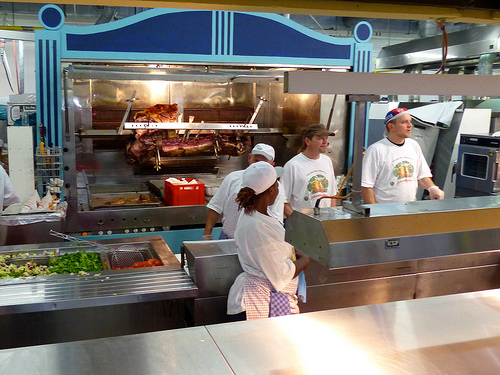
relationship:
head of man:
[391, 106, 415, 138] [353, 92, 451, 208]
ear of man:
[384, 120, 392, 134] [353, 92, 451, 208]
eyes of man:
[388, 117, 427, 125] [353, 92, 451, 208]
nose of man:
[408, 126, 414, 127] [353, 92, 451, 208]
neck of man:
[390, 140, 408, 147] [353, 92, 451, 208]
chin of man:
[401, 134, 413, 142] [353, 92, 451, 208]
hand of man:
[422, 187, 459, 200] [353, 92, 451, 208]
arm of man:
[359, 191, 372, 207] [353, 92, 451, 208]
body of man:
[225, 175, 233, 230] [353, 92, 451, 208]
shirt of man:
[378, 145, 417, 207] [353, 92, 451, 208]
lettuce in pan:
[51, 262, 73, 272] [109, 245, 135, 261]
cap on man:
[299, 122, 327, 137] [353, 92, 451, 208]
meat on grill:
[111, 197, 148, 201] [104, 185, 130, 191]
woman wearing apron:
[235, 176, 282, 306] [239, 290, 291, 314]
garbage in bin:
[19, 197, 43, 209] [2, 217, 51, 240]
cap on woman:
[299, 122, 327, 137] [235, 176, 282, 306]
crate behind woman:
[172, 181, 202, 204] [226, 160, 311, 322]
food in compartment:
[130, 105, 203, 165] [204, 71, 263, 94]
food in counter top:
[130, 105, 203, 165] [478, 203, 487, 245]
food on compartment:
[130, 105, 203, 165] [204, 71, 263, 94]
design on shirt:
[388, 161, 412, 186] [378, 145, 417, 207]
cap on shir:
[299, 122, 327, 137] [265, 161, 327, 180]